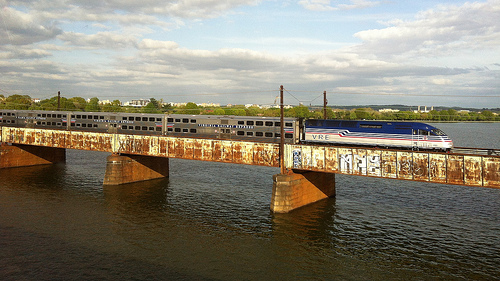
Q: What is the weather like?
A: It is cloudy.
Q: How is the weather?
A: It is cloudy.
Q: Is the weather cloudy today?
A: Yes, it is cloudy.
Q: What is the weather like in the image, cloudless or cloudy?
A: It is cloudy.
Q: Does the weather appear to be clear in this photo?
A: No, it is cloudy.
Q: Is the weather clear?
A: No, it is cloudy.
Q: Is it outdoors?
A: Yes, it is outdoors.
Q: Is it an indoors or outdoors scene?
A: It is outdoors.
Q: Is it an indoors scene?
A: No, it is outdoors.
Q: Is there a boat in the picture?
A: No, there are no boats.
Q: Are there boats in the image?
A: No, there are no boats.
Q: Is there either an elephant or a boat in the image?
A: No, there are no boats or elephants.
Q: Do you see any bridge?
A: Yes, there is a bridge.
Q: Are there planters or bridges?
A: Yes, there is a bridge.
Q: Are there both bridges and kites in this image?
A: No, there is a bridge but no kites.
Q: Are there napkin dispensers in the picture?
A: No, there are no napkin dispensers.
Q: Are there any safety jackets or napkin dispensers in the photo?
A: No, there are no napkin dispensers or safety jackets.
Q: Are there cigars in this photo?
A: No, there are no cigars.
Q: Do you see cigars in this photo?
A: No, there are no cigars.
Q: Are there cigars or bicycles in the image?
A: No, there are no cigars or bicycles.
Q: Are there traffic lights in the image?
A: No, there are no traffic lights.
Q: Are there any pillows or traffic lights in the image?
A: No, there are no traffic lights or pillows.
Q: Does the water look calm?
A: Yes, the water is calm.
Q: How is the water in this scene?
A: The water is calm.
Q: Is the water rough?
A: No, the water is calm.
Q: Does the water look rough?
A: No, the water is calm.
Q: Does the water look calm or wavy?
A: The water is calm.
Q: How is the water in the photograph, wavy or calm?
A: The water is calm.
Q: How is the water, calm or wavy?
A: The water is calm.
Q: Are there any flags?
A: No, there are no flags.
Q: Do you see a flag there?
A: No, there are no flags.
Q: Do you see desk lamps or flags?
A: No, there are no flags or desk lamps.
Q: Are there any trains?
A: Yes, there is a train.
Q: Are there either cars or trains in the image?
A: Yes, there is a train.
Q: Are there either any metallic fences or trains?
A: Yes, there is a metal train.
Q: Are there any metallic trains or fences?
A: Yes, there is a metal train.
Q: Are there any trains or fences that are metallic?
A: Yes, the train is metallic.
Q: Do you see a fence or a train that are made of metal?
A: Yes, the train is made of metal.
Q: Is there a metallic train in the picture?
A: Yes, there is a metal train.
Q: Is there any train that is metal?
A: Yes, there is a metal train.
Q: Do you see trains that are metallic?
A: Yes, there is a train that is metallic.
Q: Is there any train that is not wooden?
A: Yes, there is a metallic train.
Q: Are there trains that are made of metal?
A: Yes, there is a train that is made of metal.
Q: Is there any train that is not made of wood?
A: Yes, there is a train that is made of metal.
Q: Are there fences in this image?
A: No, there are no fences.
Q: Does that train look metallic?
A: Yes, the train is metallic.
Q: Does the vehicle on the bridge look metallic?
A: Yes, the train is metallic.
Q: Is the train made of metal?
A: Yes, the train is made of metal.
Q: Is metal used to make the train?
A: Yes, the train is made of metal.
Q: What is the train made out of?
A: The train is made of metal.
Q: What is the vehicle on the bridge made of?
A: The train is made of metal.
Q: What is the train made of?
A: The train is made of metal.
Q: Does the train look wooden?
A: No, the train is metallic.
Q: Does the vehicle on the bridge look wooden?
A: No, the train is metallic.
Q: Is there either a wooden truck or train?
A: No, there is a train but it is metallic.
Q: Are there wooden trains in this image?
A: No, there is a train but it is metallic.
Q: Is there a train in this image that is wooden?
A: No, there is a train but it is metallic.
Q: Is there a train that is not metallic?
A: No, there is a train but it is metallic.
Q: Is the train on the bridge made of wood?
A: No, the train is made of metal.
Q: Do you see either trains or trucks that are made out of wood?
A: No, there is a train but it is made of metal.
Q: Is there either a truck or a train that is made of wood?
A: No, there is a train but it is made of metal.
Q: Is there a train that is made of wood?
A: No, there is a train but it is made of metal.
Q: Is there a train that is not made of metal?
A: No, there is a train but it is made of metal.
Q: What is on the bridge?
A: The train is on the bridge.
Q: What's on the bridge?
A: The train is on the bridge.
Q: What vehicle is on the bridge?
A: The vehicle is a train.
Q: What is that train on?
A: The train is on the bridge.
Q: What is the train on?
A: The train is on the bridge.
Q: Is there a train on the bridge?
A: Yes, there is a train on the bridge.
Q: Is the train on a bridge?
A: Yes, the train is on a bridge.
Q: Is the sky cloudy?
A: Yes, the sky is cloudy.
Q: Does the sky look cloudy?
A: Yes, the sky is cloudy.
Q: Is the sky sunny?
A: No, the sky is cloudy.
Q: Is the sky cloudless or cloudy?
A: The sky is cloudy.